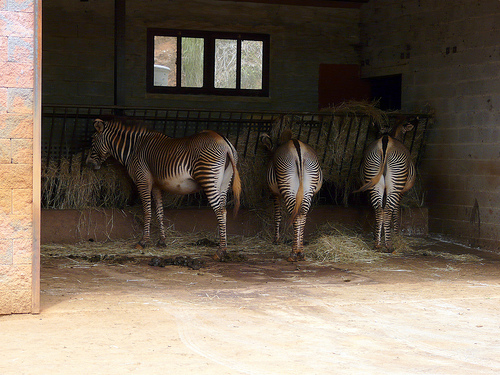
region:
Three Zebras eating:
[70, 90, 441, 279]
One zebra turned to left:
[72, 103, 252, 246]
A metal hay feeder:
[51, 105, 106, 195]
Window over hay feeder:
[137, 17, 262, 103]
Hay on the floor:
[315, 220, 360, 265]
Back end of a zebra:
[260, 125, 332, 230]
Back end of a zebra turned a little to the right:
[367, 122, 418, 247]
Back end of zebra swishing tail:
[354, 130, 418, 242]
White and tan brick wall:
[446, 75, 492, 223]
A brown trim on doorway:
[21, 0, 48, 317]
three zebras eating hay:
[70, 112, 485, 279]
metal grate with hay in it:
[43, 123, 91, 220]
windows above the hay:
[117, 15, 284, 113]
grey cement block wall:
[431, 65, 473, 155]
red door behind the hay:
[314, 63, 385, 110]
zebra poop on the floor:
[142, 245, 214, 277]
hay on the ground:
[314, 219, 364, 264]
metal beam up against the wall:
[102, 12, 133, 103]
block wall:
[2, 55, 44, 260]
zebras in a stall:
[80, 86, 441, 233]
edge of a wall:
[454, 178, 468, 202]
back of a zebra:
[283, 163, 285, 171]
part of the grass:
[347, 231, 362, 251]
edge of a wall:
[23, 213, 62, 268]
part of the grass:
[253, 142, 269, 158]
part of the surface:
[300, 320, 322, 354]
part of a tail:
[283, 228, 288, 242]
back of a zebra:
[286, 165, 297, 179]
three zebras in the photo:
[36, 76, 484, 245]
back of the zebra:
[196, 137, 256, 201]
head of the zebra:
[71, 102, 131, 174]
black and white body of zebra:
[134, 130, 209, 184]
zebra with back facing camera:
[241, 110, 338, 251]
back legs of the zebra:
[275, 211, 335, 261]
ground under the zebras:
[186, 274, 295, 339]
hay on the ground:
[230, 218, 272, 267]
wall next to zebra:
[413, 108, 494, 200]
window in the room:
[127, 10, 294, 100]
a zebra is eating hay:
[82, 115, 240, 257]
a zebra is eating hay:
[258, 133, 318, 263]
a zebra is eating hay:
[349, 120, 420, 252]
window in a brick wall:
[147, 30, 207, 92]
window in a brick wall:
[210, 32, 268, 94]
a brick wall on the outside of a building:
[0, 0, 32, 315]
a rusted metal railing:
[31, 0, 39, 315]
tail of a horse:
[227, 151, 243, 218]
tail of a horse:
[292, 160, 305, 212]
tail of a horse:
[356, 136, 389, 189]